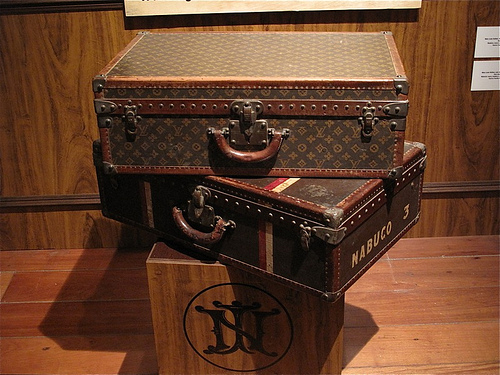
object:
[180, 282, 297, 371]
writing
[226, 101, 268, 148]
lock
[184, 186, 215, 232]
lock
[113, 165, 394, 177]
trim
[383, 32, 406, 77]
trim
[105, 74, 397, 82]
trim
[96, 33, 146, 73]
trim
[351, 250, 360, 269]
letters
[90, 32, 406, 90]
frames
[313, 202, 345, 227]
frames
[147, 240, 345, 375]
square box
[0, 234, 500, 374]
brown floor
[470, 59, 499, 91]
cards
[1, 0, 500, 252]
wall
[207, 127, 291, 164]
handle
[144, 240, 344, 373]
block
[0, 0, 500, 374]
room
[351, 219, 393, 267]
nabuco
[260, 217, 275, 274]
bands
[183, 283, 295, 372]
black logo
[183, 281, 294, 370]
circular rim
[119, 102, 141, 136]
latches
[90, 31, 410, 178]
box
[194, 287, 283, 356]
engraving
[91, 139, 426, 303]
luggage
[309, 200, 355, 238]
corner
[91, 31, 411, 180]
design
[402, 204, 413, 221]
3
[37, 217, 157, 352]
shadow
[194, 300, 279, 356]
letters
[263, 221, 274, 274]
stripes